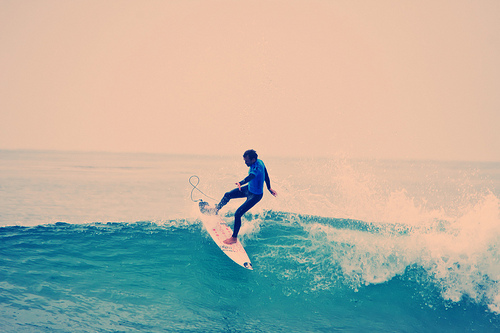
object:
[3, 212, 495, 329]
wave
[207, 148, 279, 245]
surfer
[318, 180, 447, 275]
wave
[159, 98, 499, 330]
surfing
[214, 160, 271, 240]
costume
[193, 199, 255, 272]
surfboard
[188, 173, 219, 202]
cord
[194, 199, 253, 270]
board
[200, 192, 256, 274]
white board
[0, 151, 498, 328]
water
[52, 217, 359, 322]
ocean spray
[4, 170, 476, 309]
ocean wave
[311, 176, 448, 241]
mist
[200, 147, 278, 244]
he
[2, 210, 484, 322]
ocean